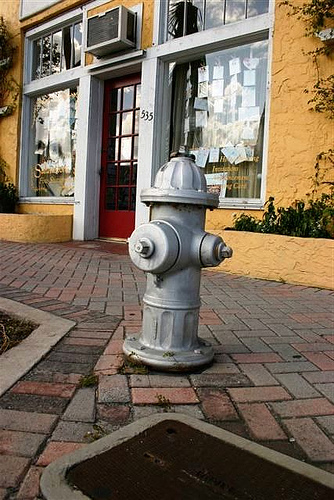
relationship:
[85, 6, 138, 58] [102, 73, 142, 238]
ac above door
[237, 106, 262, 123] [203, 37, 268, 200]
picture in window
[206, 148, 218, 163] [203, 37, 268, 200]
picture in window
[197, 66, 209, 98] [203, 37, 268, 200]
picture on window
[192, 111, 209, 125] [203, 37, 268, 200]
picture on window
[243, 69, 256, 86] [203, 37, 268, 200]
picture on window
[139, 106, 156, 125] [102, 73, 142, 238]
535 by door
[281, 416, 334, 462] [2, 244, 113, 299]
brick on sidewalk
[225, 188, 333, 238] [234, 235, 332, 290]
plants in planter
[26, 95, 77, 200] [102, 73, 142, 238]
window around door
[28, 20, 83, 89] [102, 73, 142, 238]
window around door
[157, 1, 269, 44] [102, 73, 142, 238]
window around door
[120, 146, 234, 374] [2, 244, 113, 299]
hydrant on sidewalk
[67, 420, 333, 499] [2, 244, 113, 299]
grate on sidewalk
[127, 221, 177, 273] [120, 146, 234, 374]
cap on hydrant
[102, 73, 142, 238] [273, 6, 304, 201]
door on building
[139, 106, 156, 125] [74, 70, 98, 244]
535 on trim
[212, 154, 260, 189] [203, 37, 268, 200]
letters on window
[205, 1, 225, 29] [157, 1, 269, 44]
panel on window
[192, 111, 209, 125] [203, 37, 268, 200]
picture in window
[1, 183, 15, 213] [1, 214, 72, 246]
plant in planter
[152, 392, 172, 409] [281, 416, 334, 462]
grass in brick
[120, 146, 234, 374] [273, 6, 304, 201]
hydrant in front of building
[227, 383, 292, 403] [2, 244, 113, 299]
brick on sidewalk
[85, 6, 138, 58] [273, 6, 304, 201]
ac on building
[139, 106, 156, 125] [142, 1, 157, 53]
535 on wall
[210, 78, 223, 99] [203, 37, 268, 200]
picture in window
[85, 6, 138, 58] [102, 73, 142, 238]
ac over door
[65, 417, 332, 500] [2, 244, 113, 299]
sewer on sidewalk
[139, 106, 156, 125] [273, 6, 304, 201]
number on building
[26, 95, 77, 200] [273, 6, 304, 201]
window on building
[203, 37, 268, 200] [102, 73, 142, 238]
window by door